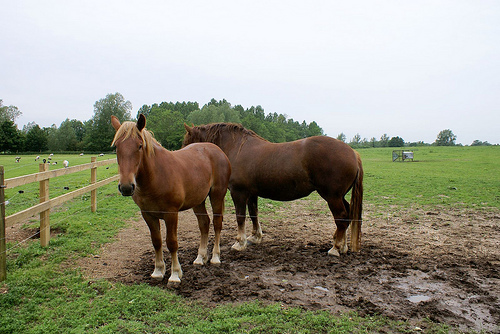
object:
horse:
[105, 110, 231, 287]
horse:
[179, 120, 373, 255]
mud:
[131, 235, 498, 333]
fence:
[0, 154, 126, 282]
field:
[0, 138, 500, 332]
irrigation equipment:
[388, 147, 418, 163]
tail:
[349, 149, 367, 253]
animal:
[62, 159, 71, 169]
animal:
[79, 152, 85, 157]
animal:
[13, 156, 23, 163]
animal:
[33, 155, 40, 162]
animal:
[49, 152, 54, 157]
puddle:
[406, 295, 429, 304]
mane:
[106, 120, 162, 155]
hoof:
[166, 279, 182, 290]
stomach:
[180, 181, 211, 210]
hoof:
[150, 275, 164, 283]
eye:
[114, 143, 121, 153]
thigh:
[140, 210, 160, 232]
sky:
[0, 0, 499, 147]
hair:
[181, 120, 260, 147]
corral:
[62, 193, 500, 333]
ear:
[135, 112, 148, 132]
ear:
[104, 112, 123, 132]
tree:
[18, 118, 56, 154]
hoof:
[229, 246, 242, 253]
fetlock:
[153, 257, 167, 269]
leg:
[192, 199, 211, 267]